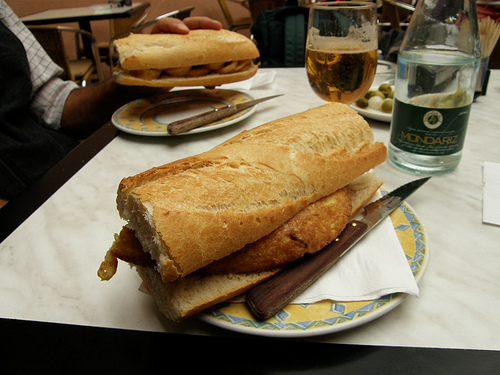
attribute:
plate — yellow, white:
[89, 85, 266, 149]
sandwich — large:
[104, 10, 266, 101]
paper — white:
[0, 64, 495, 332]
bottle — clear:
[383, 4, 493, 177]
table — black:
[28, 50, 482, 372]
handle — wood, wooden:
[239, 223, 376, 317]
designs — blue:
[210, 89, 248, 128]